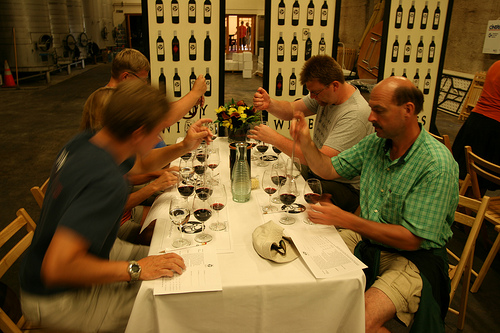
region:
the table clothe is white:
[231, 215, 258, 290]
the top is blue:
[11, 157, 111, 282]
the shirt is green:
[366, 157, 448, 232]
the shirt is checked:
[351, 144, 440, 221]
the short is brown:
[386, 265, 423, 310]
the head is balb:
[376, 72, 422, 90]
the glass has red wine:
[187, 190, 221, 245]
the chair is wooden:
[459, 187, 491, 263]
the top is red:
[478, 70, 492, 113]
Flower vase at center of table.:
[205, 93, 268, 212]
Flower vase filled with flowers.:
[212, 89, 270, 212]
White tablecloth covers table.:
[121, 117, 368, 331]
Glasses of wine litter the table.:
[154, 107, 319, 251]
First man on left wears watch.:
[11, 70, 193, 331]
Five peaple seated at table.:
[17, 45, 461, 328]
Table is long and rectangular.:
[121, 106, 376, 331]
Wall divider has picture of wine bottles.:
[135, 35, 228, 159]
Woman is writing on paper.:
[47, 83, 204, 230]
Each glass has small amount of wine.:
[158, 112, 332, 237]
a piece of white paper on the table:
[297, 231, 359, 279]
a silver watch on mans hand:
[126, 262, 146, 274]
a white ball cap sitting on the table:
[257, 217, 288, 265]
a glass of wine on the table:
[194, 192, 215, 232]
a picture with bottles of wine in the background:
[156, 2, 211, 58]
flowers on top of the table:
[219, 105, 256, 142]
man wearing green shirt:
[346, 80, 455, 228]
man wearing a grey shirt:
[303, 54, 360, 147]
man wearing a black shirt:
[49, 89, 163, 273]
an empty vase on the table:
[234, 146, 256, 203]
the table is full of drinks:
[174, 112, 296, 292]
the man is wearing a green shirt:
[343, 139, 448, 245]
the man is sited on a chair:
[451, 199, 490, 300]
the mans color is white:
[393, 118, 407, 128]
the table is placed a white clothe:
[202, 262, 313, 319]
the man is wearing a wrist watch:
[128, 257, 141, 287]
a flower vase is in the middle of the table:
[222, 104, 249, 149]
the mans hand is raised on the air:
[177, 71, 203, 109]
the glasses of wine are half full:
[182, 180, 317, 216]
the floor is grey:
[42, 89, 74, 131]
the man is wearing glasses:
[295, 55, 360, 123]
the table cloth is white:
[196, 232, 385, 329]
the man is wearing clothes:
[352, 150, 477, 330]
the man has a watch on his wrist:
[115, 252, 163, 292]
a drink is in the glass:
[183, 180, 250, 245]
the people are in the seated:
[57, 35, 475, 330]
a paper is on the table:
[275, 225, 380, 293]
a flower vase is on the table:
[214, 77, 269, 217]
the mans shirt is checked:
[343, 143, 477, 259]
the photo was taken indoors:
[4, 3, 499, 330]